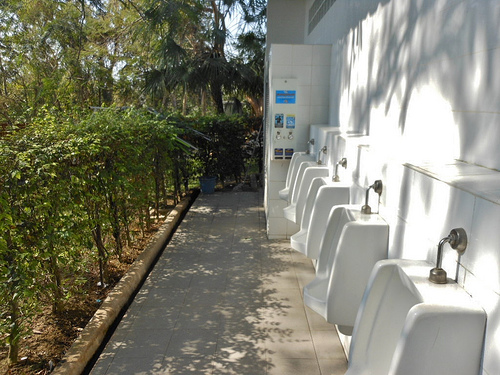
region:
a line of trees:
[8, 114, 125, 359]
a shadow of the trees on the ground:
[166, 193, 255, 368]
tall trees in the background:
[10, 15, 286, 85]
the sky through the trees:
[220, 25, 255, 66]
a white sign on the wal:
[272, 82, 294, 159]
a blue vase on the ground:
[202, 170, 222, 186]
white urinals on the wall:
[280, 151, 442, 371]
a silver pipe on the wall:
[433, 230, 458, 291]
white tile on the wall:
[350, 30, 490, 176]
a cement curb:
[78, 199, 151, 367]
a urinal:
[299, 262, 350, 313]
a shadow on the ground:
[177, 260, 267, 344]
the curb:
[89, 308, 115, 327]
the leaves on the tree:
[52, 135, 135, 178]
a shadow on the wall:
[363, 60, 440, 121]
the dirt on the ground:
[70, 273, 99, 304]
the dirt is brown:
[20, 321, 67, 354]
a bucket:
[198, 173, 219, 192]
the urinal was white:
[315, 255, 350, 321]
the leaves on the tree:
[27, 149, 103, 189]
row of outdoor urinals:
[275, 138, 488, 374]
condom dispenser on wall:
[271, 74, 301, 162]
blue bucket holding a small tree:
[196, 166, 220, 196]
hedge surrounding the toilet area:
[0, 105, 258, 370]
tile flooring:
[136, 184, 305, 373]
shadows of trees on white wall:
[314, 27, 494, 179]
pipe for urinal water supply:
[426, 225, 472, 287]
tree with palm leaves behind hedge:
[136, 0, 266, 129]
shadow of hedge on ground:
[179, 225, 296, 370]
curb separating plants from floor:
[48, 183, 203, 374]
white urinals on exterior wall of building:
[274, 133, 486, 373]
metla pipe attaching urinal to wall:
[422, 218, 469, 289]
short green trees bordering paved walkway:
[1, 115, 198, 374]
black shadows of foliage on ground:
[88, 176, 297, 372]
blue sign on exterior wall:
[272, 85, 297, 110]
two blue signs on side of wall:
[267, 110, 304, 135]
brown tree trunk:
[200, 79, 235, 116]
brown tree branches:
[198, 3, 227, 34]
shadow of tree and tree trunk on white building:
[373, 155, 438, 259]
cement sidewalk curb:
[46, 186, 196, 373]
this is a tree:
[12, 127, 78, 333]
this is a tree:
[41, 103, 128, 295]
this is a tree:
[97, 93, 159, 223]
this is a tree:
[162, 113, 189, 207]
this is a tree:
[196, 109, 255, 178]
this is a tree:
[41, 6, 161, 225]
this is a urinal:
[357, 247, 427, 367]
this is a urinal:
[305, 208, 370, 316]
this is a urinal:
[289, 178, 339, 253]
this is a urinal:
[276, 145, 322, 217]